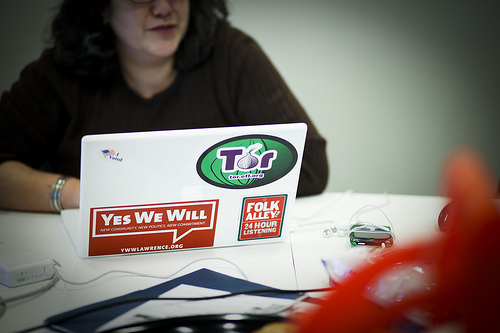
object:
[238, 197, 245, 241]
line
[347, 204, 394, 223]
lien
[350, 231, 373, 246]
part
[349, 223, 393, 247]
box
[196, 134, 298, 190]
sticker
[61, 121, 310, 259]
laptop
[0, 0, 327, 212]
woman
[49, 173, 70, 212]
bracelet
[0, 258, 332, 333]
wire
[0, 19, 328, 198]
shirt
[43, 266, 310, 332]
booklet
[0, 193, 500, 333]
table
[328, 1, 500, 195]
wall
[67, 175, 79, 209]
wrist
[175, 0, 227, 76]
hair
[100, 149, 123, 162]
sticker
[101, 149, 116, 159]
flag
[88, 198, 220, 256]
sticker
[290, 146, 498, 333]
item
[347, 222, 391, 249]
headphones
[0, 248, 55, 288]
brick